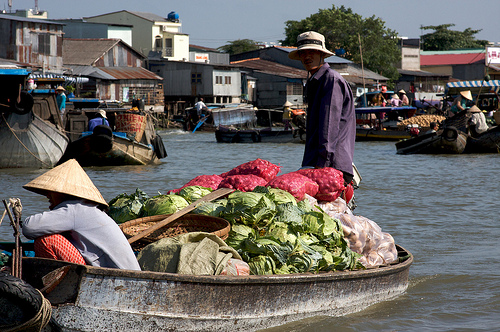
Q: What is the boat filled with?
A: Produce.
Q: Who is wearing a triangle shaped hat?
A: The man.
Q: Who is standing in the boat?
A: A man.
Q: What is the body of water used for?
A: Boats.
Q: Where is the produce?
A: On top of a boat.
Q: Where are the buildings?
A: Behind the water.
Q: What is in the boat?
A: Food items.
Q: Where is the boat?
A: In the water.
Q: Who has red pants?
A: The man crouched down.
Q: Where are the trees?
A: Behind the buildings.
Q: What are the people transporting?
A: Food.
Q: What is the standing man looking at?
A: The camera.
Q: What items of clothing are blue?
A: Shirts.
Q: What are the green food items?
A: Cabbage.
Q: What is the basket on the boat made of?
A: Wood.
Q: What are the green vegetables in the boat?
A: Lettuce.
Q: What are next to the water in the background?
A: Buildings and businesses.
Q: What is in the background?
A: A body of water full of boats.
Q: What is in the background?
A: Buildings.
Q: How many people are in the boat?
A: Two.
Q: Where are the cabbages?
A: In the boat.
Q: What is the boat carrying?
A: Cabbages.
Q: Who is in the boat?
A: The two people.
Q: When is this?
A: Daytime.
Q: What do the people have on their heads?
A: Hats.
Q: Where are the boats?
A: In the water.